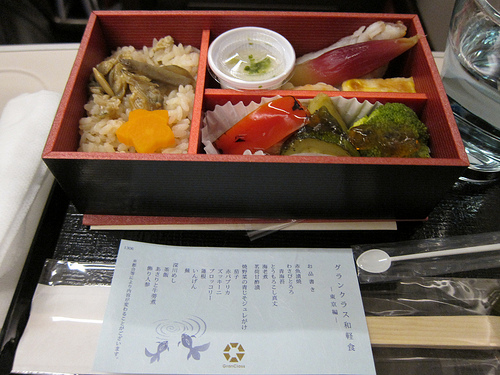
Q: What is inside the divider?
A: Asian food.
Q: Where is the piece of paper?
A: On the table.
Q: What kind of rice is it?
A: Steamed white rice.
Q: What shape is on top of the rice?
A: A star.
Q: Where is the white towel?
A: On the counter.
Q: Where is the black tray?
A: Under the food.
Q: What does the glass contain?
A: Water.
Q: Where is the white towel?
A: On the white counter.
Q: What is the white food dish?
A: Rice.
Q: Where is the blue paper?
A: On the black tray.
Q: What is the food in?
A: Red divided box.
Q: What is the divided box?
A: A bento.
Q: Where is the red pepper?
A: In the vegetable dish.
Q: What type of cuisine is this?
A: Japanese.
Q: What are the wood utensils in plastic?
A: Chopsticks.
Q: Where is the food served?
A: Bento box.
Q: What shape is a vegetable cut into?
A: Star.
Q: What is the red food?
A: Bell pepper.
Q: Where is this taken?
A: A restaurant.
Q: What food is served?
A: Vegetables.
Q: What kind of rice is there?
A: Brown.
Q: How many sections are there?
A: Three.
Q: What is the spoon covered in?
A: Plastic.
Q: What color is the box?
A: Black and red.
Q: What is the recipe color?
A: Blue.